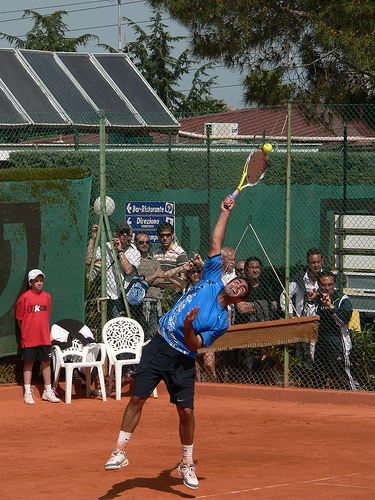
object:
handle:
[224, 189, 240, 209]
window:
[332, 212, 375, 313]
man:
[152, 222, 189, 316]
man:
[86, 221, 141, 317]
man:
[306, 270, 355, 391]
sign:
[125, 200, 176, 244]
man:
[104, 194, 252, 490]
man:
[133, 232, 165, 331]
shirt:
[137, 253, 163, 300]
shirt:
[152, 241, 188, 315]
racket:
[224, 148, 269, 209]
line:
[194, 460, 373, 499]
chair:
[102, 316, 158, 400]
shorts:
[129, 328, 196, 410]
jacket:
[50, 318, 102, 389]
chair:
[50, 318, 109, 403]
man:
[234, 256, 278, 325]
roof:
[19, 99, 375, 149]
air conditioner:
[203, 121, 238, 146]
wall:
[0, 144, 375, 360]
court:
[0, 375, 375, 499]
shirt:
[16, 289, 52, 349]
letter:
[27, 304, 47, 312]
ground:
[220, 394, 361, 497]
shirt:
[159, 253, 229, 359]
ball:
[263, 141, 273, 154]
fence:
[0, 102, 375, 395]